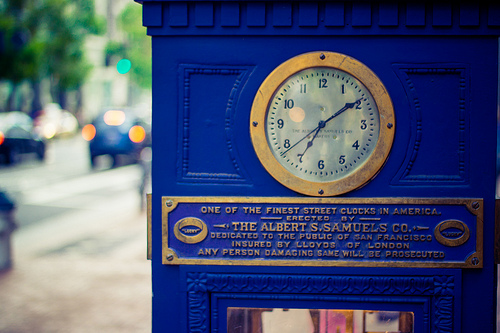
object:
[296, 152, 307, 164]
number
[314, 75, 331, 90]
number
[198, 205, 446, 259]
words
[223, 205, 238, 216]
word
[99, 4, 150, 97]
trees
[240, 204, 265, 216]
word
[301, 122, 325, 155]
hand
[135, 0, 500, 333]
object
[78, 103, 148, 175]
cars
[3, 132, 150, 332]
street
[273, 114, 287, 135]
number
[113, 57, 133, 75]
green trafficlight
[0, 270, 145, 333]
ground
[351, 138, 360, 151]
number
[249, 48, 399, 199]
clock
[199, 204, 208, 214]
letters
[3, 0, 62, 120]
tree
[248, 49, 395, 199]
rim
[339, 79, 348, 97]
number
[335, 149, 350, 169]
number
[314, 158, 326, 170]
number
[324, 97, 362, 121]
hands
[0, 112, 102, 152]
sidewalk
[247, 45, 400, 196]
trim